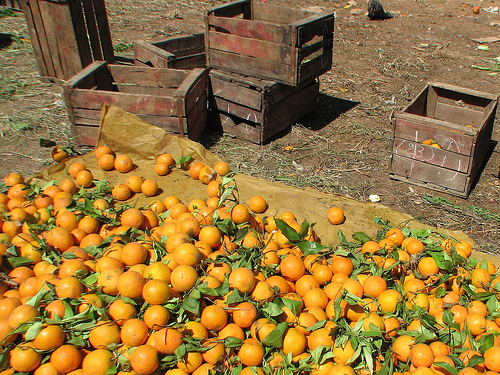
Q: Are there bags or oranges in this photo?
A: Yes, there are oranges.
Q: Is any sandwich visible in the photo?
A: No, there are no sandwiches.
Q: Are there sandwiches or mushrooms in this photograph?
A: No, there are no sandwiches or mushrooms.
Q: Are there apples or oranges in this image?
A: Yes, there are oranges.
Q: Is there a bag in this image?
A: Yes, there is a bag.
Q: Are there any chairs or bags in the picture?
A: Yes, there is a bag.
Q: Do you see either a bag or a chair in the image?
A: Yes, there is a bag.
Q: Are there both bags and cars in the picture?
A: No, there is a bag but no cars.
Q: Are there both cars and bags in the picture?
A: No, there is a bag but no cars.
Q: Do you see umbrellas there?
A: No, there are no umbrellas.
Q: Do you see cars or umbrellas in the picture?
A: No, there are no umbrellas or cars.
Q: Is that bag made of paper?
A: Yes, the bag is made of paper.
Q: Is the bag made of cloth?
A: No, the bag is made of paper.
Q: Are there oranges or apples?
A: Yes, there are oranges.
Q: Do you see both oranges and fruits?
A: Yes, there are both oranges and a fruit.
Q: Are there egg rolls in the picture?
A: No, there are no egg rolls.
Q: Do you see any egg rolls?
A: No, there are no egg rolls.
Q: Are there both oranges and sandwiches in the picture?
A: No, there are oranges but no sandwiches.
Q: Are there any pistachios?
A: No, there are no pistachios.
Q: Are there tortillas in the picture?
A: No, there are no tortillas.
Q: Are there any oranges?
A: Yes, there are oranges.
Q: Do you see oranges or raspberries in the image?
A: Yes, there are oranges.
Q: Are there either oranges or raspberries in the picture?
A: Yes, there are oranges.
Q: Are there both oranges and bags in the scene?
A: Yes, there are both oranges and a bag.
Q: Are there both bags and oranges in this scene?
A: Yes, there are both oranges and a bag.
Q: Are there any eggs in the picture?
A: No, there are no eggs.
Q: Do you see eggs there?
A: No, there are no eggs.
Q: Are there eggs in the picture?
A: No, there are no eggs.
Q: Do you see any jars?
A: No, there are no jars.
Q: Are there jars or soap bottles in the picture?
A: No, there are no jars or soap bottles.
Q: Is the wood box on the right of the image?
A: Yes, the box is on the right of the image.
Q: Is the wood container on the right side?
A: Yes, the box is on the right of the image.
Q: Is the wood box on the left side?
A: No, the box is on the right of the image.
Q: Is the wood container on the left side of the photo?
A: No, the box is on the right of the image.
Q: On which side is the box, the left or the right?
A: The box is on the right of the image.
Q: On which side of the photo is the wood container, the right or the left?
A: The box is on the right of the image.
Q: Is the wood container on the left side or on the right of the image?
A: The box is on the right of the image.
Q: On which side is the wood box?
A: The box is on the right of the image.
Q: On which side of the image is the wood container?
A: The box is on the right of the image.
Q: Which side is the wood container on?
A: The box is on the right of the image.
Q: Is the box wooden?
A: Yes, the box is wooden.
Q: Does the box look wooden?
A: Yes, the box is wooden.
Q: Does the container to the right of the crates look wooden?
A: Yes, the box is wooden.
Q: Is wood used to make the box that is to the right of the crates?
A: Yes, the box is made of wood.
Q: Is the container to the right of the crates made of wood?
A: Yes, the box is made of wood.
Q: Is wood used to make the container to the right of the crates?
A: Yes, the box is made of wood.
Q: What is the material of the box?
A: The box is made of wood.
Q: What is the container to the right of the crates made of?
A: The box is made of wood.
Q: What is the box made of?
A: The box is made of wood.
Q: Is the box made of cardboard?
A: No, the box is made of wood.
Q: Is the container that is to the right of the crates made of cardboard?
A: No, the box is made of wood.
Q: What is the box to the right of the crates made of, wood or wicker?
A: The box is made of wood.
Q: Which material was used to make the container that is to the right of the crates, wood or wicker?
A: The box is made of wood.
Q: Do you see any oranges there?
A: Yes, there are oranges.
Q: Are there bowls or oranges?
A: Yes, there are oranges.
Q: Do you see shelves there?
A: No, there are no shelves.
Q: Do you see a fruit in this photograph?
A: Yes, there is a fruit.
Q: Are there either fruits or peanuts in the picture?
A: Yes, there is a fruit.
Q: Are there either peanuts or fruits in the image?
A: Yes, there is a fruit.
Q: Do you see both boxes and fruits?
A: Yes, there are both a fruit and a box.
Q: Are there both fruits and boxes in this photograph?
A: Yes, there are both a fruit and a box.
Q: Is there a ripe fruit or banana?
A: Yes, there is a ripe fruit.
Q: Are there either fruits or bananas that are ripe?
A: Yes, the fruit is ripe.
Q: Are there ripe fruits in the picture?
A: Yes, there is a ripe fruit.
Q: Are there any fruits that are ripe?
A: Yes, there is a fruit that is ripe.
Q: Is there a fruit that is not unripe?
A: Yes, there is an ripe fruit.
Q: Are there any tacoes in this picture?
A: No, there are no tacoes.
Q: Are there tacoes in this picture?
A: No, there are no tacoes.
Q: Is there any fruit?
A: Yes, there is a fruit.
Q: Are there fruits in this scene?
A: Yes, there is a fruit.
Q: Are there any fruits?
A: Yes, there is a fruit.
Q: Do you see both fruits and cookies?
A: No, there is a fruit but no cookies.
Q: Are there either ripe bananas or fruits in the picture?
A: Yes, there is a ripe fruit.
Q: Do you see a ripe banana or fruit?
A: Yes, there is a ripe fruit.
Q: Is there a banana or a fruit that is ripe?
A: Yes, the fruit is ripe.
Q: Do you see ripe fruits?
A: Yes, there is a ripe fruit.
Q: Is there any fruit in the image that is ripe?
A: Yes, there is a fruit that is ripe.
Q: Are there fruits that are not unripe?
A: Yes, there is an ripe fruit.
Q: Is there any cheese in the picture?
A: No, there is no cheese.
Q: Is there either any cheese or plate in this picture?
A: No, there are no cheese or plates.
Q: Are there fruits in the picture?
A: Yes, there is a fruit.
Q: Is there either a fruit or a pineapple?
A: Yes, there is a fruit.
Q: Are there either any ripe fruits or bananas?
A: Yes, there is a ripe fruit.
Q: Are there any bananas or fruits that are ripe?
A: Yes, the fruit is ripe.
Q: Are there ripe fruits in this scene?
A: Yes, there is a ripe fruit.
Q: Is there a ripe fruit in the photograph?
A: Yes, there is a ripe fruit.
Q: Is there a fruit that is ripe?
A: Yes, there is a fruit that is ripe.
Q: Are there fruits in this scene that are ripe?
A: Yes, there is a fruit that is ripe.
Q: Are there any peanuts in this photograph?
A: No, there are no peanuts.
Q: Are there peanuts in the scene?
A: No, there are no peanuts.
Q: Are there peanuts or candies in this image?
A: No, there are no peanuts or candies.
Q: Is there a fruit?
A: Yes, there is a fruit.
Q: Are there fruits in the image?
A: Yes, there is a fruit.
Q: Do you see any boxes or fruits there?
A: Yes, there is a fruit.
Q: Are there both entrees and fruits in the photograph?
A: No, there is a fruit but no entrees.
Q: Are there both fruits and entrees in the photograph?
A: No, there is a fruit but no entrees.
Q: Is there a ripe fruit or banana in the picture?
A: Yes, there is a ripe fruit.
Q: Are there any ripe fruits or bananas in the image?
A: Yes, there is a ripe fruit.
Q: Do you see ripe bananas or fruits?
A: Yes, there is a ripe fruit.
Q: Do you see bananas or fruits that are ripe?
A: Yes, the fruit is ripe.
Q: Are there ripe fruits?
A: Yes, there is a ripe fruit.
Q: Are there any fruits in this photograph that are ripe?
A: Yes, there is a fruit that is ripe.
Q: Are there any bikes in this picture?
A: No, there are no bikes.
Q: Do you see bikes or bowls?
A: No, there are no bikes or bowls.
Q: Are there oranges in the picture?
A: Yes, there are oranges.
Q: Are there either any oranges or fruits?
A: Yes, there are oranges.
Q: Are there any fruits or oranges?
A: Yes, there are oranges.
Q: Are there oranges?
A: Yes, there are oranges.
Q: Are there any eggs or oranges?
A: Yes, there are oranges.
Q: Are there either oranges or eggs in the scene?
A: Yes, there are oranges.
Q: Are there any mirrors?
A: No, there are no mirrors.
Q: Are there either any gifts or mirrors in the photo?
A: No, there are no mirrors or gifts.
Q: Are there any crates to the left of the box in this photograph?
A: Yes, there are crates to the left of the box.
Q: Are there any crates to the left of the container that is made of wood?
A: Yes, there are crates to the left of the box.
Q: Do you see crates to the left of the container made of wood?
A: Yes, there are crates to the left of the box.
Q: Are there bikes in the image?
A: No, there are no bikes.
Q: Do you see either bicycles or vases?
A: No, there are no bicycles or vases.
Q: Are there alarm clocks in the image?
A: No, there are no alarm clocks.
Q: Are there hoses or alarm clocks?
A: No, there are no alarm clocks or hoses.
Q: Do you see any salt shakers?
A: No, there are no salt shakers.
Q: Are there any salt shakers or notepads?
A: No, there are no salt shakers or notepads.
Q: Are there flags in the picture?
A: No, there are no flags.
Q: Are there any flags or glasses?
A: No, there are no flags or glasses.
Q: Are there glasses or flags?
A: No, there are no flags or glasses.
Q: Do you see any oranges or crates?
A: Yes, there are oranges.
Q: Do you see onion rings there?
A: No, there are no onion rings.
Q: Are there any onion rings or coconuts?
A: No, there are no onion rings or coconuts.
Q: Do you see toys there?
A: No, there are no toys.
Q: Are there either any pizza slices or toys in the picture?
A: No, there are no toys or pizza slices.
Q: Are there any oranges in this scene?
A: Yes, there are oranges.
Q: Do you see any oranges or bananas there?
A: Yes, there are oranges.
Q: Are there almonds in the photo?
A: No, there are no almonds.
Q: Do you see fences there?
A: No, there are no fences.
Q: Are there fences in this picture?
A: No, there are no fences.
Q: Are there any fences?
A: No, there are no fences.